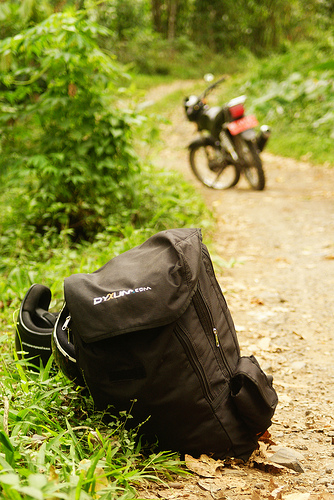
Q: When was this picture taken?
A: Daytime.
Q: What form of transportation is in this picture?
A: Bicycle.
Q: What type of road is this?
A: Dirt road.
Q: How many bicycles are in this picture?
A: 1.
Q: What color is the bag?
A: Black.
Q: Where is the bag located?
A: On ground.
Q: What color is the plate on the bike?
A: Red.